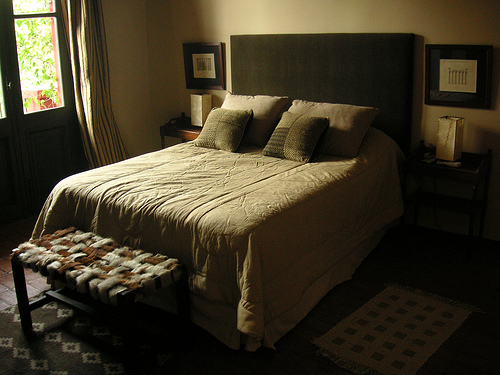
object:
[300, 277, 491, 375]
rug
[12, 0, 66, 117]
window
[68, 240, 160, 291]
strips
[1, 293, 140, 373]
rug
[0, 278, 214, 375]
rug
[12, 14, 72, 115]
pane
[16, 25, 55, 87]
leaves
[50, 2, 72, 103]
railing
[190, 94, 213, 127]
lamp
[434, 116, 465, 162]
lamp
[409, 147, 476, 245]
nightstand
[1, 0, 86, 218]
door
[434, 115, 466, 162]
lampshade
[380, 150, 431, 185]
ground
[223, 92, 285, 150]
pillows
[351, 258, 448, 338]
floor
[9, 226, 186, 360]
stool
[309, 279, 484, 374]
carpet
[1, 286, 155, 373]
carpet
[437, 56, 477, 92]
image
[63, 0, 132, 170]
curtain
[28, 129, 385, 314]
comforter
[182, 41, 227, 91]
picture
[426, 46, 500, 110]
picture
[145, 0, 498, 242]
wall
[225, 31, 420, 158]
head board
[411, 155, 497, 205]
nightstand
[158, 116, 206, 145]
nightstand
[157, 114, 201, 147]
night table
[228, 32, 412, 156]
fabric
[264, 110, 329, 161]
pillows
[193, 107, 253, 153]
pillows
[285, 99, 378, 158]
pillows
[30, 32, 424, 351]
bed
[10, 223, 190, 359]
bench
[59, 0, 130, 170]
stripes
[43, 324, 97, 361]
pattern